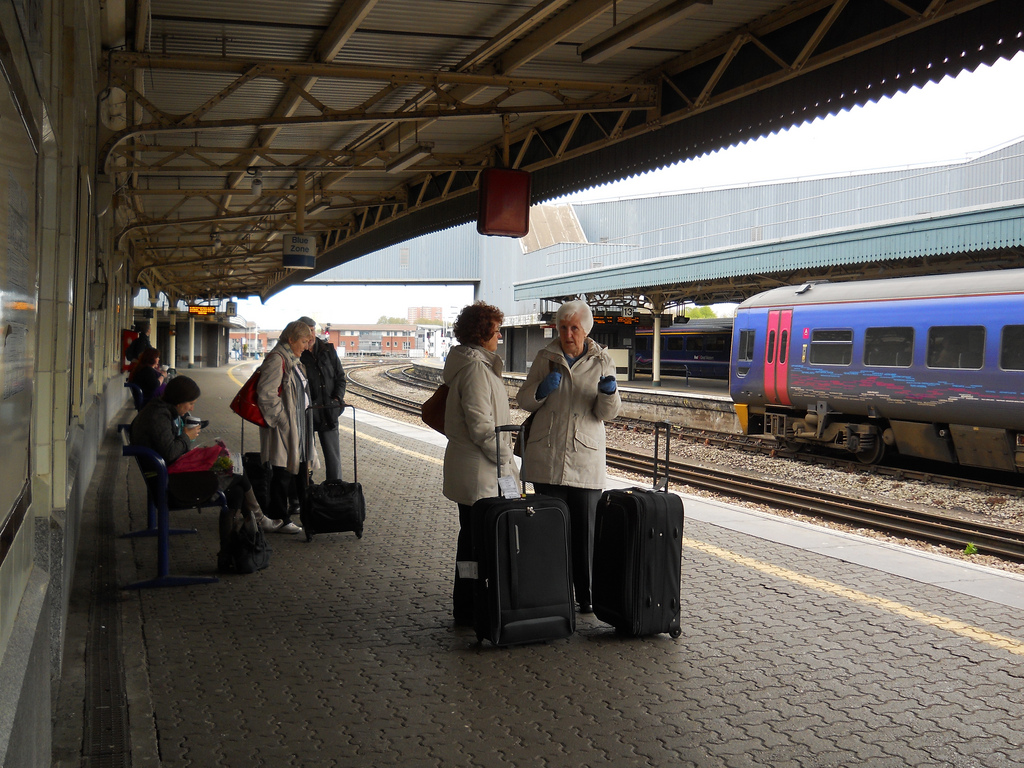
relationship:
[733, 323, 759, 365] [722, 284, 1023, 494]
window on train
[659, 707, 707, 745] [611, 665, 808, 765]
stone on floor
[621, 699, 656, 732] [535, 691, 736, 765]
stone on floor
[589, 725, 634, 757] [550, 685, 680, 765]
stone on floor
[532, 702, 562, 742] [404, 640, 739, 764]
stone on floor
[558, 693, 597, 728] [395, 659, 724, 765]
stone on floor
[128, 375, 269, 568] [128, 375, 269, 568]
woman on bench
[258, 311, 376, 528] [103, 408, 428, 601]
people on platform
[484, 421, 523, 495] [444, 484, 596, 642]
handle on suitcase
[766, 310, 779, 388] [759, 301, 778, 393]
train has doors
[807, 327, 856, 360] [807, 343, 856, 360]
window on train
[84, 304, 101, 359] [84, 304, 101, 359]
wall on building